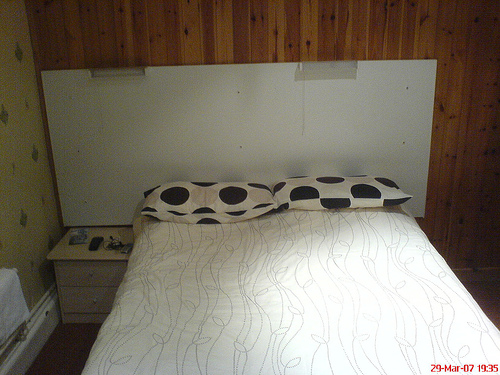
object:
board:
[38, 58, 440, 227]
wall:
[28, 0, 500, 270]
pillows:
[140, 181, 276, 223]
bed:
[80, 200, 500, 375]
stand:
[47, 226, 135, 325]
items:
[88, 236, 104, 252]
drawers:
[52, 261, 128, 287]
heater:
[0, 262, 30, 357]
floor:
[24, 322, 103, 375]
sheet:
[80, 204, 499, 375]